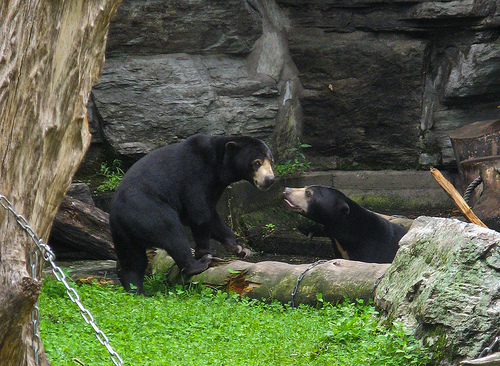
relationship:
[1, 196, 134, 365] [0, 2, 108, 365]
chain on tree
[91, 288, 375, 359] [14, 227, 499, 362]
foliage on ground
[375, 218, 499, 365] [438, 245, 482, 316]
boulder has moss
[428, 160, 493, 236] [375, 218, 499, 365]
stick on boulder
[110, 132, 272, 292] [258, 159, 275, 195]
bear with tan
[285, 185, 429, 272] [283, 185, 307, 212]
bear with tan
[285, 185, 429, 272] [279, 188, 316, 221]
bear has mouth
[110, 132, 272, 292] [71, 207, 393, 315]
bear standing on log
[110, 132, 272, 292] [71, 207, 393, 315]
bear on log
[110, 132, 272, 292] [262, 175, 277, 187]
bear has nose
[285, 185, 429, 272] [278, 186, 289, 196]
bear has nose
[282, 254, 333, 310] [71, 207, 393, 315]
chain on log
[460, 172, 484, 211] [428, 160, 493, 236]
rope by stick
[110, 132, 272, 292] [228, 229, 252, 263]
bear has paw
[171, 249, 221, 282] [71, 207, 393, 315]
foot on log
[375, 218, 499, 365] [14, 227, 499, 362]
boulder on ground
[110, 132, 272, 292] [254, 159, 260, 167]
bear has eye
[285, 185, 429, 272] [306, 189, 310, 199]
bear has eye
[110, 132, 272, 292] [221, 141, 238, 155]
bear has ear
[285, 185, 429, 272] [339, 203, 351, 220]
bear has ear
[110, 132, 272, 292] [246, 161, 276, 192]
bear has snout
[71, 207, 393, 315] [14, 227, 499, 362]
log on ground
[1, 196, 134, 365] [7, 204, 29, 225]
chain in metal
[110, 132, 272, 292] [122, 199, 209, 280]
bear has leg